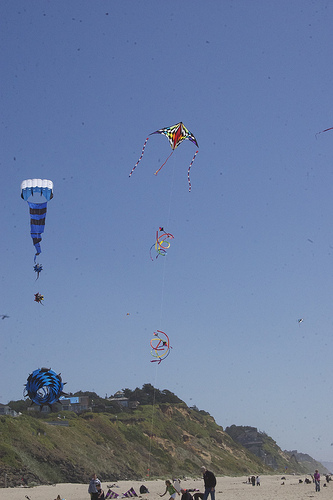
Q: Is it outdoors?
A: Yes, it is outdoors.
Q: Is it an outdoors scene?
A: Yes, it is outdoors.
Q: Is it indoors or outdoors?
A: It is outdoors.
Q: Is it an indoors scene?
A: No, it is outdoors.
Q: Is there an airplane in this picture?
A: Yes, there is an airplane.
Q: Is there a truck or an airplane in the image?
A: Yes, there is an airplane.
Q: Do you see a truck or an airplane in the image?
A: Yes, there is an airplane.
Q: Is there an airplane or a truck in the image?
A: Yes, there is an airplane.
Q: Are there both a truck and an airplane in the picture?
A: No, there is an airplane but no trucks.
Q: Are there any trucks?
A: No, there are no trucks.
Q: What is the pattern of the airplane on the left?
A: The plane is striped.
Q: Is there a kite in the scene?
A: Yes, there is a kite.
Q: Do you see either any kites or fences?
A: Yes, there is a kite.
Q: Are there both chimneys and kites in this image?
A: No, there is a kite but no chimneys.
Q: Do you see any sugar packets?
A: No, there are no sugar packets.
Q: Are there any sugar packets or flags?
A: No, there are no sugar packets or flags.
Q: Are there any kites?
A: Yes, there is a kite.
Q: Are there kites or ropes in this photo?
A: Yes, there is a kite.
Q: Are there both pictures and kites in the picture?
A: No, there is a kite but no pictures.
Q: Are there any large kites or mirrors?
A: Yes, there is a large kite.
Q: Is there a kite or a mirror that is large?
A: Yes, the kite is large.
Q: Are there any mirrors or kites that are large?
A: Yes, the kite is large.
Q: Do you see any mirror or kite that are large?
A: Yes, the kite is large.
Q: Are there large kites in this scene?
A: Yes, there is a large kite.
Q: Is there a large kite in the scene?
A: Yes, there is a large kite.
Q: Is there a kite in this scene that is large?
A: Yes, there is a kite that is large.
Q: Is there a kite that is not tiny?
A: Yes, there is a large kite.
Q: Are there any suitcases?
A: No, there are no suitcases.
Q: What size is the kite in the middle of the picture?
A: The kite is large.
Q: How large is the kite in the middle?
A: The kite is large.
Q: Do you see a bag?
A: No, there are no bags.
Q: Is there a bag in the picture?
A: No, there are no bags.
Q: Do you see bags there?
A: No, there are no bags.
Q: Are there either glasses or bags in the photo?
A: No, there are no bags or glasses.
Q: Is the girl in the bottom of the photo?
A: Yes, the girl is in the bottom of the image.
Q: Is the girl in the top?
A: No, the girl is in the bottom of the image.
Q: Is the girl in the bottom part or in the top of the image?
A: The girl is in the bottom of the image.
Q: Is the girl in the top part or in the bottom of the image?
A: The girl is in the bottom of the image.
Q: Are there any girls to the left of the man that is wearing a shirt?
A: Yes, there is a girl to the left of the man.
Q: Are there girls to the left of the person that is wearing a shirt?
A: Yes, there is a girl to the left of the man.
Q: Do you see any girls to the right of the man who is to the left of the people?
A: No, the girl is to the left of the man.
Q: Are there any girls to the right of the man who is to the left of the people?
A: No, the girl is to the left of the man.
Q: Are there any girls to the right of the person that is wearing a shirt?
A: No, the girl is to the left of the man.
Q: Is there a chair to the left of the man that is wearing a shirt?
A: No, there is a girl to the left of the man.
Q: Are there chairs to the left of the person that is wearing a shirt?
A: No, there is a girl to the left of the man.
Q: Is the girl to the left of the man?
A: Yes, the girl is to the left of the man.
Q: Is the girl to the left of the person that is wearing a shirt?
A: Yes, the girl is to the left of the man.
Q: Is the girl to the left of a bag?
A: No, the girl is to the left of the man.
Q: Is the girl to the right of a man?
A: No, the girl is to the left of a man.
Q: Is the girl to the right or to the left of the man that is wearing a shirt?
A: The girl is to the left of the man.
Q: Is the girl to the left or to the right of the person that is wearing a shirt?
A: The girl is to the left of the man.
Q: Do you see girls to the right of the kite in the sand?
A: Yes, there is a girl to the right of the kite.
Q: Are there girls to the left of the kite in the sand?
A: No, the girl is to the right of the kite.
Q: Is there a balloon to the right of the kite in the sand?
A: No, there is a girl to the right of the kite.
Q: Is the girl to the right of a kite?
A: Yes, the girl is to the right of a kite.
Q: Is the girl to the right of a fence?
A: No, the girl is to the right of a kite.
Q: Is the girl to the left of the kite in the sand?
A: No, the girl is to the right of the kite.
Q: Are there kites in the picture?
A: Yes, there is a kite.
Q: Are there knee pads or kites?
A: Yes, there is a kite.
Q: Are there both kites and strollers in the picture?
A: No, there is a kite but no strollers.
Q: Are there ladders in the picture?
A: No, there are no ladders.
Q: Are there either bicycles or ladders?
A: No, there are no ladders or bicycles.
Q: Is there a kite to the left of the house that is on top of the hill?
A: Yes, there is a kite to the left of the house.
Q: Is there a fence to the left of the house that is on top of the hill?
A: No, there is a kite to the left of the house.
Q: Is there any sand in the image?
A: Yes, there is sand.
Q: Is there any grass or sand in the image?
A: Yes, there is sand.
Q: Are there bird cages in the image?
A: No, there are no bird cages.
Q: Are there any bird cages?
A: No, there are no bird cages.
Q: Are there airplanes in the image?
A: Yes, there is an airplane.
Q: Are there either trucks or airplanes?
A: Yes, there is an airplane.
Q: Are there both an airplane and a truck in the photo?
A: No, there is an airplane but no trucks.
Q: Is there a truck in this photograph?
A: No, there are no trucks.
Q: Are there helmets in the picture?
A: No, there are no helmets.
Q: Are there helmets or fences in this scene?
A: No, there are no helmets or fences.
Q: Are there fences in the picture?
A: No, there are no fences.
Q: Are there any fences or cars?
A: No, there are no fences or cars.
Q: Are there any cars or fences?
A: No, there are no fences or cars.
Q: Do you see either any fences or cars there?
A: No, there are no fences or cars.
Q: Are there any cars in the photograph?
A: No, there are no cars.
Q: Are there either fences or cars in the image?
A: No, there are no cars or fences.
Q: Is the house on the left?
A: Yes, the house is on the left of the image.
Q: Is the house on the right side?
A: No, the house is on the left of the image.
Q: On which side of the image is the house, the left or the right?
A: The house is on the left of the image.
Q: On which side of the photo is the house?
A: The house is on the left of the image.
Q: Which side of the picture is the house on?
A: The house is on the left of the image.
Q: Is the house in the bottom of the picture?
A: Yes, the house is in the bottom of the image.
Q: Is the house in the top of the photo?
A: No, the house is in the bottom of the image.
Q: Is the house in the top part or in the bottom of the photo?
A: The house is in the bottom of the image.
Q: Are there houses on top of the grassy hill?
A: Yes, there is a house on top of the hill.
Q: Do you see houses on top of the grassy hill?
A: Yes, there is a house on top of the hill.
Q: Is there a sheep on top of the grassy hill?
A: No, there is a house on top of the hill.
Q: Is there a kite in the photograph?
A: Yes, there is a kite.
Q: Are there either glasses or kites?
A: Yes, there is a kite.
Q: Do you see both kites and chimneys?
A: No, there is a kite but no chimneys.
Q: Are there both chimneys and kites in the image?
A: No, there is a kite but no chimneys.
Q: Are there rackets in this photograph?
A: No, there are no rackets.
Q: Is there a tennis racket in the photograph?
A: No, there are no rackets.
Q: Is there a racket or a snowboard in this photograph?
A: No, there are no rackets or snowboards.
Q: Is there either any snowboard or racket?
A: No, there are no rackets or snowboards.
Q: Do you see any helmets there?
A: No, there are no helmets.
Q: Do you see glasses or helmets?
A: No, there are no helmets or glasses.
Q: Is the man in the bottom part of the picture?
A: Yes, the man is in the bottom of the image.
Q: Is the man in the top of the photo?
A: No, the man is in the bottom of the image.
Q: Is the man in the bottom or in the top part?
A: The man is in the bottom of the image.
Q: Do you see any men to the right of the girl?
A: Yes, there is a man to the right of the girl.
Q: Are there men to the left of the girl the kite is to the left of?
A: No, the man is to the right of the girl.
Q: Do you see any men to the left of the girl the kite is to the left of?
A: No, the man is to the right of the girl.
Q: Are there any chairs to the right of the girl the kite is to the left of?
A: No, there is a man to the right of the girl.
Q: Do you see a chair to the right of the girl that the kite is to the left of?
A: No, there is a man to the right of the girl.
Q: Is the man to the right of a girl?
A: Yes, the man is to the right of a girl.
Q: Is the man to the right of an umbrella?
A: No, the man is to the right of a girl.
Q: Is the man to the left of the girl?
A: No, the man is to the right of the girl.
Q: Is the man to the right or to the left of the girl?
A: The man is to the right of the girl.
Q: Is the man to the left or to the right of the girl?
A: The man is to the right of the girl.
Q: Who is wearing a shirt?
A: The man is wearing a shirt.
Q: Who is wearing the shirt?
A: The man is wearing a shirt.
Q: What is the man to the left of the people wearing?
A: The man is wearing a shirt.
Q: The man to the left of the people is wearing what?
A: The man is wearing a shirt.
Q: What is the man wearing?
A: The man is wearing a shirt.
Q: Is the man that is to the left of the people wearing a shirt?
A: Yes, the man is wearing a shirt.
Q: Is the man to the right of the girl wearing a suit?
A: No, the man is wearing a shirt.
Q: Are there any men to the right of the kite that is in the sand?
A: Yes, there is a man to the right of the kite.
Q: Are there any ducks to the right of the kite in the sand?
A: No, there is a man to the right of the kite.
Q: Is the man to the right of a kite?
A: Yes, the man is to the right of a kite.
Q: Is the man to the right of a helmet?
A: No, the man is to the right of a kite.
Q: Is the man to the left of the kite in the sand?
A: No, the man is to the right of the kite.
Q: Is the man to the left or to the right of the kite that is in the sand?
A: The man is to the right of the kite.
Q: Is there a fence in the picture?
A: No, there are no fences.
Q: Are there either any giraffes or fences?
A: No, there are no fences or giraffes.